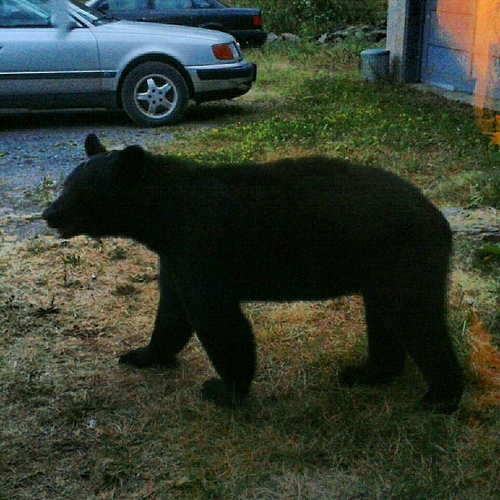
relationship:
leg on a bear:
[189, 300, 257, 401] [40, 133, 463, 418]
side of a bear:
[53, 162, 457, 406] [40, 133, 463, 418]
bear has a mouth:
[40, 133, 463, 418] [48, 187, 75, 237]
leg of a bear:
[189, 300, 257, 401] [40, 133, 463, 418]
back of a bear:
[193, 154, 392, 189] [40, 133, 463, 418]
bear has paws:
[40, 133, 463, 418] [121, 336, 248, 410]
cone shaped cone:
[355, 41, 401, 95] [361, 49, 390, 82]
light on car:
[246, 9, 259, 34] [86, 1, 271, 49]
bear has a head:
[40, 133, 463, 418] [40, 131, 138, 236]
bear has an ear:
[40, 133, 463, 418] [83, 129, 102, 157]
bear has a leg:
[40, 133, 463, 418] [189, 300, 257, 401]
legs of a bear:
[351, 284, 469, 401] [40, 133, 463, 418]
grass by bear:
[162, 7, 498, 479] [40, 133, 463, 418]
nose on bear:
[39, 204, 63, 227] [40, 133, 463, 418]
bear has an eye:
[40, 133, 463, 418] [75, 183, 94, 203]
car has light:
[1, 0, 259, 126] [208, 40, 253, 65]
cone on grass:
[361, 49, 390, 82] [162, 7, 498, 479]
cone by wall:
[361, 49, 390, 82] [384, 3, 499, 114]